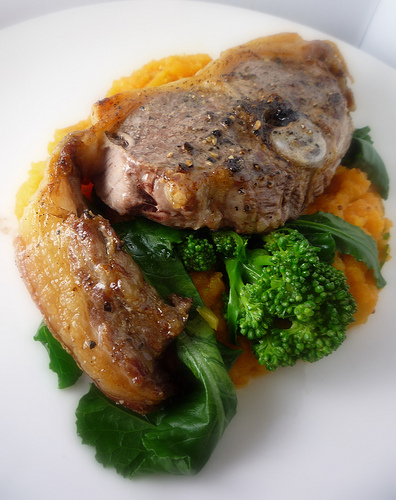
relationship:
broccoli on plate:
[230, 230, 358, 364] [2, 3, 394, 499]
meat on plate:
[90, 49, 363, 247] [2, 3, 394, 499]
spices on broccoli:
[182, 87, 292, 178] [230, 230, 358, 364]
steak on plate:
[90, 49, 363, 247] [2, 3, 394, 499]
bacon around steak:
[8, 130, 186, 419] [3, 45, 362, 417]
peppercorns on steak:
[165, 103, 266, 196] [3, 45, 362, 417]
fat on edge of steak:
[306, 34, 356, 98] [3, 45, 362, 417]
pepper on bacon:
[64, 203, 193, 375] [8, 130, 186, 419]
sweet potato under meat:
[100, 45, 213, 86] [90, 49, 363, 247]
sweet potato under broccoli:
[209, 198, 393, 361] [220, 221, 361, 377]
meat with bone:
[90, 49, 363, 247] [259, 111, 334, 176]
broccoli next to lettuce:
[133, 230, 357, 364] [168, 325, 245, 476]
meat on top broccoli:
[90, 49, 363, 247] [230, 230, 358, 364]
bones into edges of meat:
[259, 111, 334, 176] [90, 49, 363, 247]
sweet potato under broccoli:
[298, 166, 395, 364] [230, 230, 358, 364]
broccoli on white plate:
[230, 230, 358, 364] [2, 3, 394, 499]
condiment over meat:
[182, 87, 292, 178] [90, 49, 363, 247]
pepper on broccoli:
[68, 100, 263, 375] [230, 230, 358, 364]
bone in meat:
[259, 111, 334, 176] [90, 49, 363, 247]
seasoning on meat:
[165, 103, 266, 196] [90, 49, 363, 247]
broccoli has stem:
[220, 221, 361, 377] [219, 232, 270, 287]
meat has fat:
[90, 49, 363, 247] [306, 34, 356, 98]